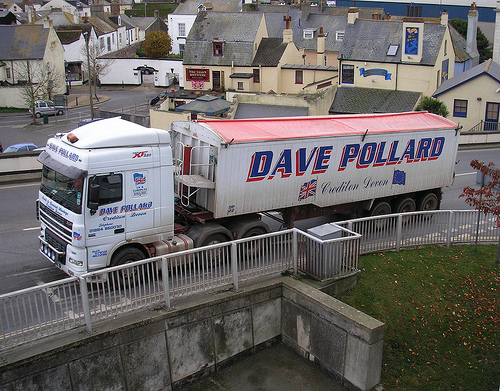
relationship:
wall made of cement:
[0, 269, 384, 390] [175, 334, 202, 361]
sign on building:
[183, 67, 211, 83] [182, 12, 339, 95]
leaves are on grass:
[419, 259, 498, 340] [330, 242, 499, 389]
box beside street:
[307, 223, 343, 278] [3, 148, 498, 338]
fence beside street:
[0, 207, 497, 360] [3, 148, 498, 338]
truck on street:
[37, 112, 462, 284] [3, 148, 498, 338]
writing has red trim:
[245, 137, 446, 180] [249, 155, 437, 181]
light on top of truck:
[66, 131, 78, 144] [37, 112, 462, 284]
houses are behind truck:
[1, 0, 498, 135] [37, 112, 462, 284]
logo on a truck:
[245, 137, 446, 180] [37, 112, 462, 284]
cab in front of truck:
[35, 114, 176, 286] [37, 112, 462, 284]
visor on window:
[35, 148, 86, 181] [39, 162, 83, 215]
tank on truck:
[150, 232, 198, 274] [37, 112, 462, 284]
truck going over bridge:
[37, 112, 462, 284] [3, 250, 373, 390]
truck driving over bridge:
[37, 112, 462, 284] [3, 250, 373, 390]